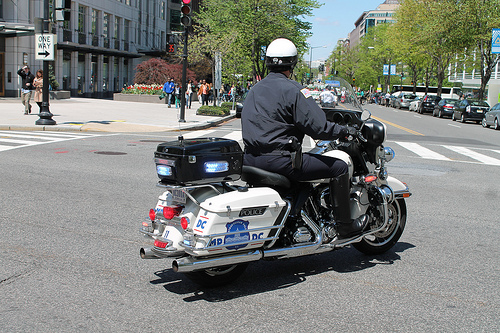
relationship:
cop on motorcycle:
[241, 36, 369, 238] [137, 104, 412, 281]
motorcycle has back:
[141, 79, 397, 273] [137, 128, 244, 277]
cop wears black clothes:
[241, 36, 369, 238] [236, 72, 353, 174]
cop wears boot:
[241, 36, 369, 238] [337, 211, 369, 238]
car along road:
[397, 90, 498, 139] [0, 87, 495, 333]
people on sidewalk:
[11, 62, 43, 114] [6, 102, 188, 136]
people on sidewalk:
[163, 76, 240, 108] [6, 102, 188, 136]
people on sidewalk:
[310, 81, 362, 103] [6, 102, 188, 136]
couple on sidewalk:
[19, 63, 43, 115] [5, 96, 219, 136]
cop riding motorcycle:
[241, 36, 369, 238] [137, 104, 412, 281]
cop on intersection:
[160, 32, 431, 272] [61, 137, 464, 304]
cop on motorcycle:
[241, 36, 369, 238] [136, 75, 413, 286]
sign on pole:
[35, 33, 53, 58] [35, 4, 56, 129]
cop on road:
[241, 36, 369, 238] [59, 123, 491, 321]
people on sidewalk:
[33, 69, 44, 112] [0, 95, 217, 132]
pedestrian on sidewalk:
[16, 64, 34, 115] [0, 95, 217, 132]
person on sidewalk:
[196, 75, 212, 104] [0, 95, 217, 132]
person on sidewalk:
[182, 77, 197, 104] [0, 95, 217, 132]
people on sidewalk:
[163, 78, 174, 107] [0, 95, 217, 132]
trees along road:
[180, 0, 499, 110] [327, 87, 499, 328]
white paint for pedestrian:
[397, 131, 497, 186] [18, 63, 50, 110]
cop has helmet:
[241, 36, 369, 238] [258, 34, 300, 67]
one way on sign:
[37, 36, 51, 48] [32, 30, 54, 62]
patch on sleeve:
[300, 85, 312, 97] [293, 80, 347, 142]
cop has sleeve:
[241, 36, 369, 238] [293, 80, 347, 142]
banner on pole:
[493, 29, 499, 49] [176, 4, 188, 122]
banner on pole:
[381, 63, 397, 77] [36, 7, 55, 126]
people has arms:
[33, 69, 44, 112] [33, 79, 42, 89]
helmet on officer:
[240, 19, 330, 74] [239, 37, 369, 237]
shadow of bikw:
[153, 238, 365, 313] [140, 74, 410, 284]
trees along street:
[184, 3, 244, 93] [390, 122, 489, 331]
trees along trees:
[428, 0, 453, 101] [184, 3, 244, 93]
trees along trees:
[447, 0, 497, 100] [184, 3, 244, 93]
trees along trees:
[387, 22, 426, 91] [184, 3, 244, 93]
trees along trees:
[365, 37, 380, 85] [184, 3, 244, 93]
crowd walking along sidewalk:
[162, 79, 239, 106] [0, 92, 238, 135]